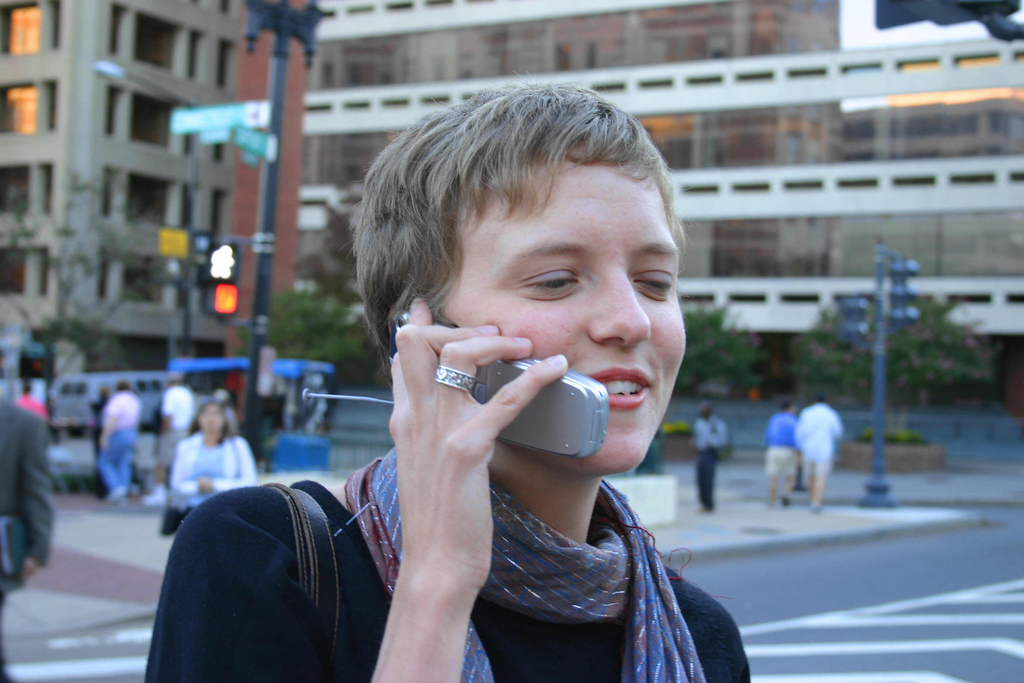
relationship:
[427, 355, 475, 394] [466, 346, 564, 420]
ring on finger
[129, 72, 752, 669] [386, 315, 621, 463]
lady on cell phone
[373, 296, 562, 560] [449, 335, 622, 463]
hand holding phone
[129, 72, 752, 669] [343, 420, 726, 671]
lady wearing scarf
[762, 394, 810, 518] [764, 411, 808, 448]
person wearing shirt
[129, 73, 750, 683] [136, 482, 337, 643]
lady wearing sleeves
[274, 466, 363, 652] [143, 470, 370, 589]
strap on shoulder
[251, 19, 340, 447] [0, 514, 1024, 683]
light pole on road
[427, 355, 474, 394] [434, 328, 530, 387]
ring on finger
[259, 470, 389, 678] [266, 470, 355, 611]
bag has strap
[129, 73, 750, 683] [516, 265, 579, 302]
lady has eye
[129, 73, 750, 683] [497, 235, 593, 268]
lady has eyebrow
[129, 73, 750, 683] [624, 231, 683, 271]
lady has eyebrown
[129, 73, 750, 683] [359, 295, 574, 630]
lady has hand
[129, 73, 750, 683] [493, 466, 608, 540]
lady has neck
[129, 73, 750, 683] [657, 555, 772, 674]
lady has shoulder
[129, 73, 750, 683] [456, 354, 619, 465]
lady on cell phone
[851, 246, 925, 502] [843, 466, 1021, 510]
lamp on sidewalk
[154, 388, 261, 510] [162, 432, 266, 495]
woman wears cardigan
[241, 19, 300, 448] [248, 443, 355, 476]
light pole on sidewalk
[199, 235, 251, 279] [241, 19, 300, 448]
sign on light pole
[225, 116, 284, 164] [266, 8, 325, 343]
sign on pole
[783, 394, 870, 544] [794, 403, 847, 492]
person in shirt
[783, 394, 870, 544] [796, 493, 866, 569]
person on sidewalk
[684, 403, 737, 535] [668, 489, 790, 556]
man on sidewalk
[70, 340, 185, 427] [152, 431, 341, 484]
bus on road